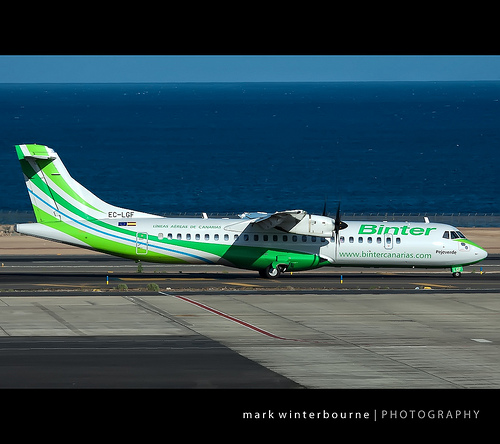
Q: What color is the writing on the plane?
A: Green.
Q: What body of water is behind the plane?
A: Ocean.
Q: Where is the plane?
A: Runway.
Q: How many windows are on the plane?
A: 24.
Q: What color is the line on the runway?
A: Red.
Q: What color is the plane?
A: Green and white.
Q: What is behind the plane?
A: The ocean.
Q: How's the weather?
A: Warm and sunny.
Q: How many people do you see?
A: No one.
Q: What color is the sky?
A: Clear blue.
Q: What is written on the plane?
A: Binter.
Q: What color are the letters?
A: Green.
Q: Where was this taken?
A: Airport.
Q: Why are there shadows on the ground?
A: Sunny.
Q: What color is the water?
A: Blue.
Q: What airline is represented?
A: Binter.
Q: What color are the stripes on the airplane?
A: Green.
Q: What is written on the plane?
A: The name of the airline.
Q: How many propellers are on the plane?
A: Two propellers.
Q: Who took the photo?
A: Mark Winterbourne did.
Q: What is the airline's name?
A: It is Binter.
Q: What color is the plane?
A: Green, blue, and white.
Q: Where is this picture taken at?
A: On a airport runway.